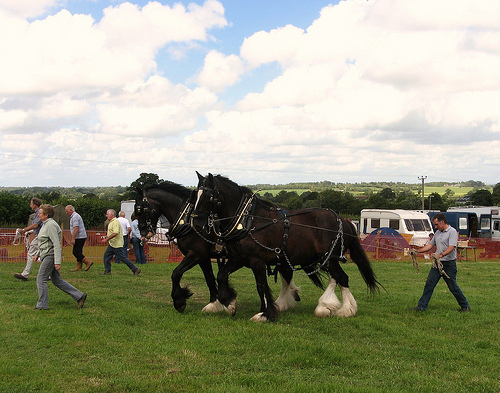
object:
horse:
[131, 174, 302, 313]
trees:
[467, 188, 497, 206]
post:
[421, 176, 426, 211]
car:
[355, 209, 434, 246]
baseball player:
[32, 203, 87, 310]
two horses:
[129, 172, 392, 321]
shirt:
[38, 217, 64, 264]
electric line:
[255, 212, 433, 256]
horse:
[187, 170, 388, 322]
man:
[409, 211, 471, 315]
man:
[104, 208, 140, 276]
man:
[14, 197, 42, 280]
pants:
[413, 259, 470, 312]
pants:
[36, 255, 83, 310]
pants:
[101, 242, 136, 276]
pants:
[129, 235, 149, 264]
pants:
[23, 251, 37, 278]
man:
[65, 205, 95, 272]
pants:
[71, 239, 87, 260]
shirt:
[106, 217, 125, 249]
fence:
[0, 227, 479, 260]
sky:
[0, 1, 499, 188]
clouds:
[244, 26, 309, 73]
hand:
[405, 245, 417, 254]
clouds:
[0, 0, 84, 21]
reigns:
[249, 212, 452, 275]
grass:
[0, 252, 497, 393]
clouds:
[200, 50, 245, 94]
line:
[1, 153, 431, 183]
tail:
[341, 217, 385, 297]